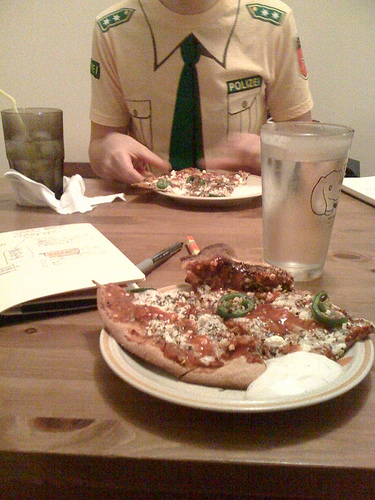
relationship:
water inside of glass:
[265, 156, 346, 267] [260, 122, 354, 283]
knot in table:
[31, 416, 98, 434] [2, 177, 372, 499]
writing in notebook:
[1, 235, 88, 270] [1, 220, 145, 316]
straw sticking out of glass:
[1, 86, 18, 114] [1, 107, 64, 201]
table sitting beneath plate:
[2, 177, 372, 499] [98, 280, 372, 413]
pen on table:
[184, 235, 203, 257] [2, 177, 372, 499]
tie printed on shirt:
[169, 36, 210, 171] [89, 1, 313, 170]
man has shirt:
[89, 0, 313, 184] [89, 1, 313, 170]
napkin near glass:
[7, 170, 126, 217] [1, 107, 64, 201]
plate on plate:
[99, 280, 374, 411] [98, 280, 372, 413]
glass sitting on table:
[260, 122, 354, 283] [2, 177, 372, 499]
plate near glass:
[98, 280, 372, 413] [260, 122, 354, 283]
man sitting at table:
[89, 0, 313, 184] [2, 177, 372, 499]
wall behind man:
[0, 0, 373, 180] [89, 0, 313, 184]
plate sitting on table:
[98, 280, 372, 413] [2, 177, 372, 499]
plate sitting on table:
[140, 168, 263, 206] [2, 177, 372, 499]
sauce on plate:
[246, 349, 345, 401] [98, 280, 372, 413]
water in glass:
[265, 156, 346, 267] [260, 122, 354, 283]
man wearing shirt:
[89, 0, 313, 184] [89, 1, 313, 170]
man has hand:
[89, 0, 313, 184] [89, 132, 173, 185]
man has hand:
[89, 0, 313, 184] [202, 131, 263, 168]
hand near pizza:
[89, 132, 173, 185] [134, 165, 250, 199]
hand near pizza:
[202, 131, 263, 168] [134, 165, 250, 199]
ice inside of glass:
[7, 129, 61, 174] [1, 107, 64, 201]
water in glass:
[7, 136, 63, 199] [1, 107, 64, 201]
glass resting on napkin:
[1, 107, 64, 201] [7, 170, 126, 217]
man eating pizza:
[89, 0, 313, 184] [134, 165, 250, 199]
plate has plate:
[98, 280, 372, 413] [99, 280, 374, 411]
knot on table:
[31, 416, 98, 434] [2, 177, 372, 499]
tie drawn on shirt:
[169, 36, 210, 171] [89, 1, 313, 170]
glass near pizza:
[260, 122, 354, 283] [94, 283, 373, 390]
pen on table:
[136, 241, 183, 274] [2, 177, 372, 499]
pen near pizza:
[136, 241, 183, 274] [94, 283, 373, 390]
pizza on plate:
[94, 283, 373, 390] [98, 280, 372, 413]